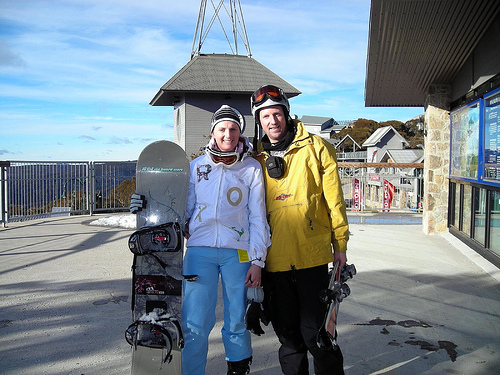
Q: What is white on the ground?
A: Snow.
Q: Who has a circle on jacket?
A: Woman with white coat.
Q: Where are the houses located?
A: Behind fence.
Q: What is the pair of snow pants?
A: Black.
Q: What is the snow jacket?
A: Yellow.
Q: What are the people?
A: A man and a woman.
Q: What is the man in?
A: A yellow jacket.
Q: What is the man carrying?
A: A pair of skis.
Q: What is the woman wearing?
A: A white ski jacket.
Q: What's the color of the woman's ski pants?
A: Blue.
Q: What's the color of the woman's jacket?
A: White.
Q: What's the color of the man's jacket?
A: Yellow.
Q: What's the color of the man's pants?
A: Black.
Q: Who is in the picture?
A: A man and woman.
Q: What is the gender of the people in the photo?
A: Male and female.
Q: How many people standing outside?
A: Two.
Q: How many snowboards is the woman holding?
A: One.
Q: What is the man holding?
A: Skis.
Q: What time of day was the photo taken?
A: Daytime.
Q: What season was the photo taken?
A: Winter.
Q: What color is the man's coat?
A: Yellow.